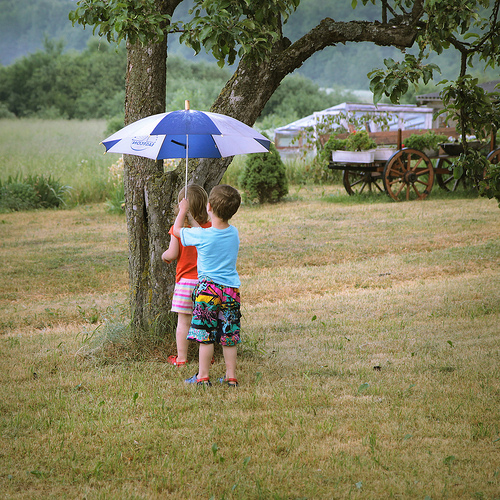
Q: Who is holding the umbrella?
A: The boy.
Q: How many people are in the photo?
A: Two.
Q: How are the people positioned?
A: With their backs to the camera.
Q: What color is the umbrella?
A: Blue and white.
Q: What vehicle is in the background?
A: A wagon.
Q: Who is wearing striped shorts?
A: The girl.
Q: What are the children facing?
A: A tree.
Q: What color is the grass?
A: Brown.